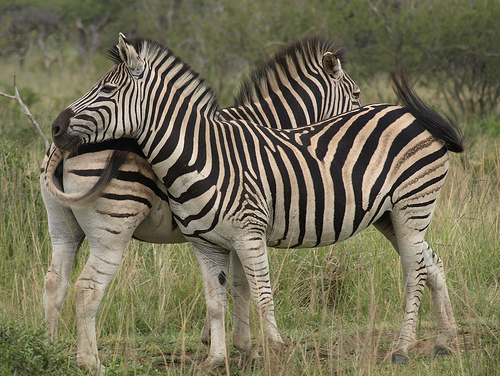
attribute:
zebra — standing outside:
[57, 34, 475, 374]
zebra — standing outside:
[33, 26, 376, 374]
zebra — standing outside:
[51, 30, 470, 351]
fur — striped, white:
[51, 22, 454, 357]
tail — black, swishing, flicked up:
[386, 52, 469, 180]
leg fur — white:
[10, 245, 235, 366]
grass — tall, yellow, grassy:
[15, 82, 494, 372]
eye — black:
[100, 77, 125, 103]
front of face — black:
[49, 98, 84, 156]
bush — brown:
[419, 42, 496, 145]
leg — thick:
[55, 146, 156, 374]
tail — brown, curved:
[21, 140, 138, 212]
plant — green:
[210, 0, 492, 85]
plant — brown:
[318, 251, 446, 373]